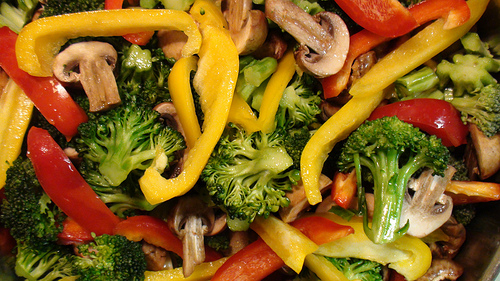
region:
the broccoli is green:
[77, 102, 159, 194]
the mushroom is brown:
[48, 35, 144, 122]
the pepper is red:
[21, 135, 104, 243]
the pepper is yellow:
[179, 38, 246, 195]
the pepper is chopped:
[189, 35, 245, 190]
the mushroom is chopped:
[46, 46, 161, 123]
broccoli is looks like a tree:
[341, 121, 424, 251]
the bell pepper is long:
[26, 133, 142, 248]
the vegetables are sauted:
[26, 25, 489, 254]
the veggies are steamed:
[28, 46, 436, 258]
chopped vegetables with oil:
[20, 14, 473, 270]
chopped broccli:
[340, 119, 461, 268]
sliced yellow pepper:
[20, 9, 205, 196]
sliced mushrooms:
[261, 3, 342, 83]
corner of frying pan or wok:
[447, 182, 498, 276]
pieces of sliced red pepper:
[25, 121, 178, 264]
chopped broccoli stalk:
[391, 64, 452, 109]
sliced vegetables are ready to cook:
[33, 9, 398, 270]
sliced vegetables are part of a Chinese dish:
[217, 33, 482, 269]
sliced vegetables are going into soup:
[88, 12, 363, 143]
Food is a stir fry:
[1, 0, 497, 278]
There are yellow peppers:
[3, 4, 490, 276]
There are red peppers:
[2, 0, 468, 278]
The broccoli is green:
[6, 9, 498, 279]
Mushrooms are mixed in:
[53, 3, 498, 279]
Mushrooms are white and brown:
[53, 1, 468, 278]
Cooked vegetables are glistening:
[1, 0, 497, 275]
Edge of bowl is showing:
[443, 186, 498, 279]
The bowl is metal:
[436, 177, 499, 279]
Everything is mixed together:
[1, 1, 499, 278]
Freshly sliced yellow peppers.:
[15, 8, 210, 78]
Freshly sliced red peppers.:
[24, 125, 135, 252]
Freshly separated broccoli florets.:
[201, 120, 296, 215]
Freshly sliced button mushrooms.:
[51, 36, 126, 119]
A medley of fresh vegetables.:
[3, 7, 497, 279]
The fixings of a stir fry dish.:
[3, 2, 498, 279]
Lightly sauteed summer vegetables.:
[0, 5, 499, 278]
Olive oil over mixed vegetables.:
[3, 0, 499, 280]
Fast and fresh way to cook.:
[1, 0, 497, 278]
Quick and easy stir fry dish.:
[1, 0, 498, 279]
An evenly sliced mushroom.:
[263, 9, 351, 76]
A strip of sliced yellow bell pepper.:
[172, 36, 239, 203]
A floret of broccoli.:
[340, 123, 437, 234]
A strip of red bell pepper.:
[17, 118, 114, 235]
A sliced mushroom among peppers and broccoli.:
[57, 42, 124, 112]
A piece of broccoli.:
[207, 134, 295, 219]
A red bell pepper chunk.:
[400, 92, 470, 137]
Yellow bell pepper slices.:
[140, 32, 236, 202]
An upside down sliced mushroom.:
[405, 167, 470, 242]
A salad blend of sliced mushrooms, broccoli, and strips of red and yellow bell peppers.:
[1, 1, 497, 276]